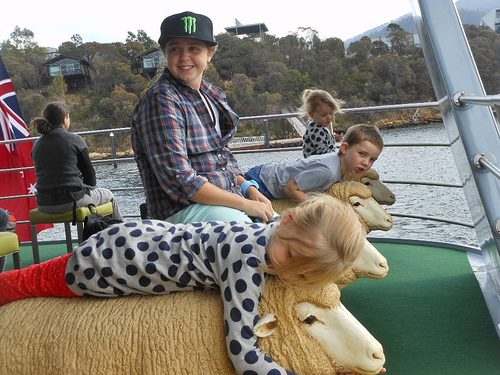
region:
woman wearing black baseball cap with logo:
[153, 10, 219, 85]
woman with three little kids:
[114, 5, 386, 298]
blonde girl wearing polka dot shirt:
[73, 193, 355, 373]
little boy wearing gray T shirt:
[271, 124, 389, 194]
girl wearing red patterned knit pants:
[0, 190, 372, 302]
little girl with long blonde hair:
[272, 195, 368, 291]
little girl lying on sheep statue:
[3, 194, 405, 374]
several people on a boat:
[6, 5, 470, 368]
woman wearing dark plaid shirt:
[136, 10, 277, 216]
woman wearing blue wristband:
[139, 8, 271, 213]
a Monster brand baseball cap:
[158, 9, 214, 45]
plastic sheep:
[0, 279, 386, 374]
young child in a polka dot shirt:
[65, 198, 361, 299]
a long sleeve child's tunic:
[65, 218, 284, 373]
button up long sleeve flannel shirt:
[131, 74, 238, 216]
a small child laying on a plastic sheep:
[245, 123, 383, 217]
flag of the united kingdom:
[0, 55, 29, 152]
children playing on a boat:
[2, 10, 497, 374]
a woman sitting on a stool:
[28, 101, 114, 221]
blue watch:
[237, 178, 260, 197]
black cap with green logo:
[157, 10, 216, 44]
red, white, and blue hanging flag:
[0, 57, 55, 242]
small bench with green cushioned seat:
[28, 200, 112, 264]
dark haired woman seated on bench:
[28, 101, 123, 234]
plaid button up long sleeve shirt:
[131, 67, 241, 226]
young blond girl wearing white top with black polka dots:
[0, 193, 367, 373]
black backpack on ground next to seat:
[81, 203, 123, 243]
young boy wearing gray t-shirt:
[243, 123, 383, 204]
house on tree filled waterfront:
[43, 53, 93, 91]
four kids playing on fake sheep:
[0, 11, 395, 373]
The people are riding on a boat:
[41, 2, 466, 372]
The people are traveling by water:
[68, 8, 463, 361]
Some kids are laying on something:
[100, 0, 462, 367]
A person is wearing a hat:
[128, 5, 235, 85]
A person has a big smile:
[125, 0, 231, 100]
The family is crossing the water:
[128, 3, 461, 348]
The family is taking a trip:
[110, 13, 460, 353]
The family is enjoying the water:
[131, 5, 438, 355]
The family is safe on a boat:
[121, 2, 482, 353]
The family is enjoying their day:
[125, 8, 455, 373]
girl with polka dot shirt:
[55, 197, 374, 339]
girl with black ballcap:
[148, 5, 223, 86]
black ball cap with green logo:
[152, 6, 222, 84]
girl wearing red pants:
[3, 197, 366, 315]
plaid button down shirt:
[132, 67, 247, 217]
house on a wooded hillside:
[8, 33, 134, 113]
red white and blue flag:
[1, 53, 50, 241]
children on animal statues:
[72, 13, 404, 370]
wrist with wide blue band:
[234, 165, 275, 212]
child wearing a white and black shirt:
[296, 84, 341, 160]